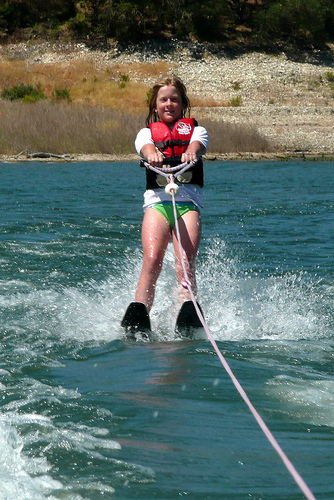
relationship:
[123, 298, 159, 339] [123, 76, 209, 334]
foot of girl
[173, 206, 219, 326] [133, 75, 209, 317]
leg of girl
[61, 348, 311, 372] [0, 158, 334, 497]
waves on water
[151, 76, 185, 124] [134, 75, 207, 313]
head of woman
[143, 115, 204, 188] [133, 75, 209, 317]
vest of girl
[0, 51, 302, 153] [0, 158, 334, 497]
grass behind water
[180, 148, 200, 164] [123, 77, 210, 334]
hand of woman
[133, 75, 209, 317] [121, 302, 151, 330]
girl on skis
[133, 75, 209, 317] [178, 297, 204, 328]
girl on skis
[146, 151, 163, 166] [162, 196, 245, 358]
hand holding rope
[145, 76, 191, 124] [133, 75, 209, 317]
head of girl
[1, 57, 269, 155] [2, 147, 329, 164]
grass on shore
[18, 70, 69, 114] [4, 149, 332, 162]
bushes on shore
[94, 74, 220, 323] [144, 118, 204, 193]
girl in life jacket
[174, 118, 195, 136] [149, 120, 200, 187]
symbol on life jacket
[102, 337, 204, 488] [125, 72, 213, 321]
shadow of skier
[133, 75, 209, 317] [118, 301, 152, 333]
girl using skis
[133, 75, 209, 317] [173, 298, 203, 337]
girl using skis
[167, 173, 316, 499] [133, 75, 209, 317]
rope pulling girl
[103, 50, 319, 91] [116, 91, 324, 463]
hillside next to lake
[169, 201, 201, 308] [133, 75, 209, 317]
leg on girl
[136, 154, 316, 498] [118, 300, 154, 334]
rope of ski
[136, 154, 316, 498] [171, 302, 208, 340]
rope of ski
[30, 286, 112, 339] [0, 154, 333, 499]
waves on lake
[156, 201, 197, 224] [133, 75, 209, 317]
bikini on girl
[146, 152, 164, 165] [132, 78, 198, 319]
hand on girl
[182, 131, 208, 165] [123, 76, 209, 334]
hand on girl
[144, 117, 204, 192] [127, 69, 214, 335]
vest on girl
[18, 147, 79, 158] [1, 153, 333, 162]
wood on shore